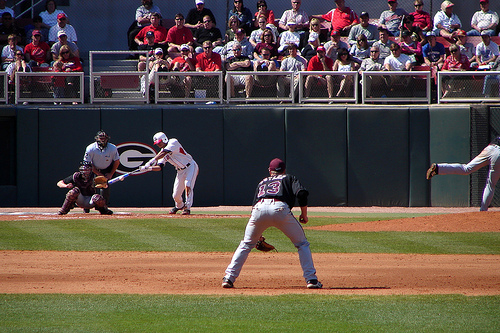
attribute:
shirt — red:
[409, 11, 437, 32]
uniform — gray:
[219, 174, 320, 282]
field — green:
[2, 206, 499, 332]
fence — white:
[0, 71, 499, 104]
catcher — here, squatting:
[55, 161, 114, 215]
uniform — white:
[156, 138, 200, 210]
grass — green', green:
[2, 212, 499, 256]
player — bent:
[152, 131, 201, 217]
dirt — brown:
[1, 251, 499, 295]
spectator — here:
[357, 45, 388, 75]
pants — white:
[173, 157, 200, 209]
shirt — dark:
[256, 173, 309, 209]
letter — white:
[277, 174, 285, 180]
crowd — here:
[2, 1, 497, 96]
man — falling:
[425, 143, 498, 212]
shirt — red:
[26, 44, 50, 62]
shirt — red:
[197, 53, 220, 71]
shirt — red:
[310, 55, 331, 70]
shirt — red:
[167, 24, 191, 45]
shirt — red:
[329, 9, 354, 30]